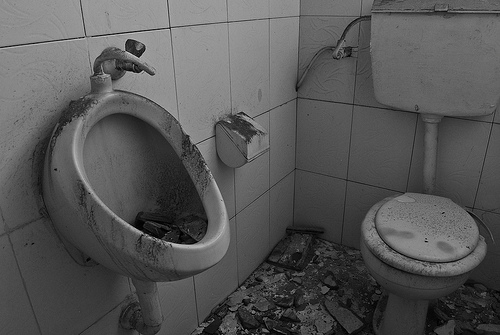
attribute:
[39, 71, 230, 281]
urinal — dirty, broken, large, round, dusty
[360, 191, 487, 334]
toilet — white, porcelain, filthy, sooty, dirty, broken, small, round, closed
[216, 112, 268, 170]
holder — metal, white, little, square, dirty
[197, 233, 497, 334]
debris — pieces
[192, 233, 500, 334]
floor — broken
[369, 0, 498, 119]
tank — porcelain, white, square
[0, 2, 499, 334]
wall — stained, white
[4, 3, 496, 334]
tile — white, square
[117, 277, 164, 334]
pipe — folded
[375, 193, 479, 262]
cover — crooked, dirty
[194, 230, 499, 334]
tile — broken, dusty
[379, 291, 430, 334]
base — dirty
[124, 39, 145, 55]
knob — black